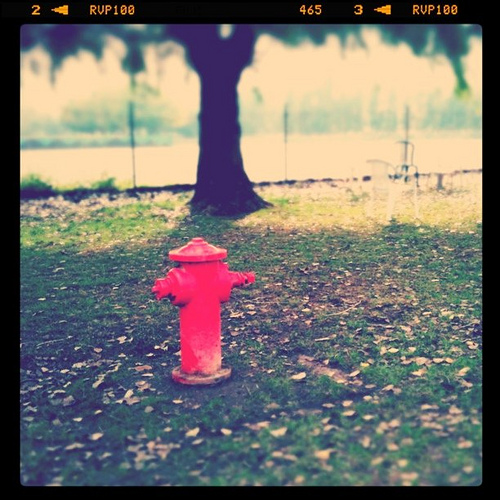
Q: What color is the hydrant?
A: Red.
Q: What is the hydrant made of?
A: Metal.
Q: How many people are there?
A: None.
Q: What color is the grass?
A: Green.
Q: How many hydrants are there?
A: One.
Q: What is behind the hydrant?
A: A tree.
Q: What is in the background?
A: A fence.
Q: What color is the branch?
A: Brown.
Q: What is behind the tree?
A: A fence.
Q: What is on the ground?
A: Leaves.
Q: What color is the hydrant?
A: Red.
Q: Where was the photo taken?
A: In a park area.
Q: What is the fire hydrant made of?
A: Metal.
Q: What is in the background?
A: A tree.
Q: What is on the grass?
A: A fire hydrant.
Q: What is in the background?
A: A fence.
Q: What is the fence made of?
A: Metal.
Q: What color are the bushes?
A: Green.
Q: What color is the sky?
A: White.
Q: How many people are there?
A: None.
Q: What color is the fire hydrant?
A: Red.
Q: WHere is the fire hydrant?
A: In the middle of the grass.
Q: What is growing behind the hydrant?
A: A tall tree.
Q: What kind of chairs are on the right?
A: Plastic chairs.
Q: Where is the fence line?
A: Behind the tree and chairs.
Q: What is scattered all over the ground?
A: Brown leaves.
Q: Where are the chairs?
A: On the right.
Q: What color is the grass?
A: Green.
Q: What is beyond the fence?
A: A body of water.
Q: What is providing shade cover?
A: The tree.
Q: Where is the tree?
A: Behind the fire hydrant.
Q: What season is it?
A: Fall.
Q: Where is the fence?
A: Behind the tree.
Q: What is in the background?
A: Fence.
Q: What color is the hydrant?
A: Red.